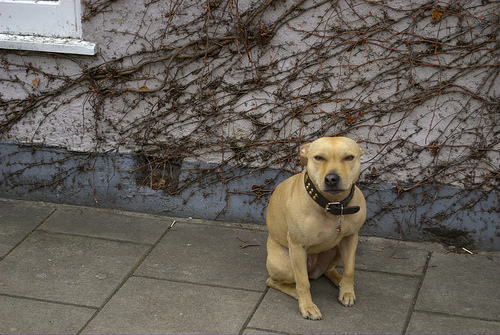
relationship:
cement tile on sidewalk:
[1, 230, 159, 308] [1, 194, 499, 328]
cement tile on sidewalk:
[114, 274, 193, 321] [28, 186, 390, 324]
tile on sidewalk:
[365, 237, 402, 292] [388, 254, 487, 321]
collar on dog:
[304, 169, 360, 215] [259, 137, 370, 321]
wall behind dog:
[0, 0, 495, 249] [263, 134, 369, 307]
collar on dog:
[304, 169, 360, 215] [209, 122, 398, 327]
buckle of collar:
[323, 199, 345, 219] [302, 170, 358, 217]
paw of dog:
[296, 299, 323, 321] [259, 137, 370, 321]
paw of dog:
[324, 265, 342, 287] [259, 137, 370, 321]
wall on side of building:
[0, 0, 499, 249] [3, 2, 499, 258]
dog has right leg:
[259, 137, 370, 321] [287, 245, 320, 320]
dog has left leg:
[259, 137, 370, 321] [335, 231, 361, 293]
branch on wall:
[0, 3, 312, 139] [0, 0, 495, 249]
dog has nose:
[259, 132, 370, 322] [323, 170, 340, 187]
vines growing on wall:
[2, 1, 499, 245] [0, 0, 495, 249]